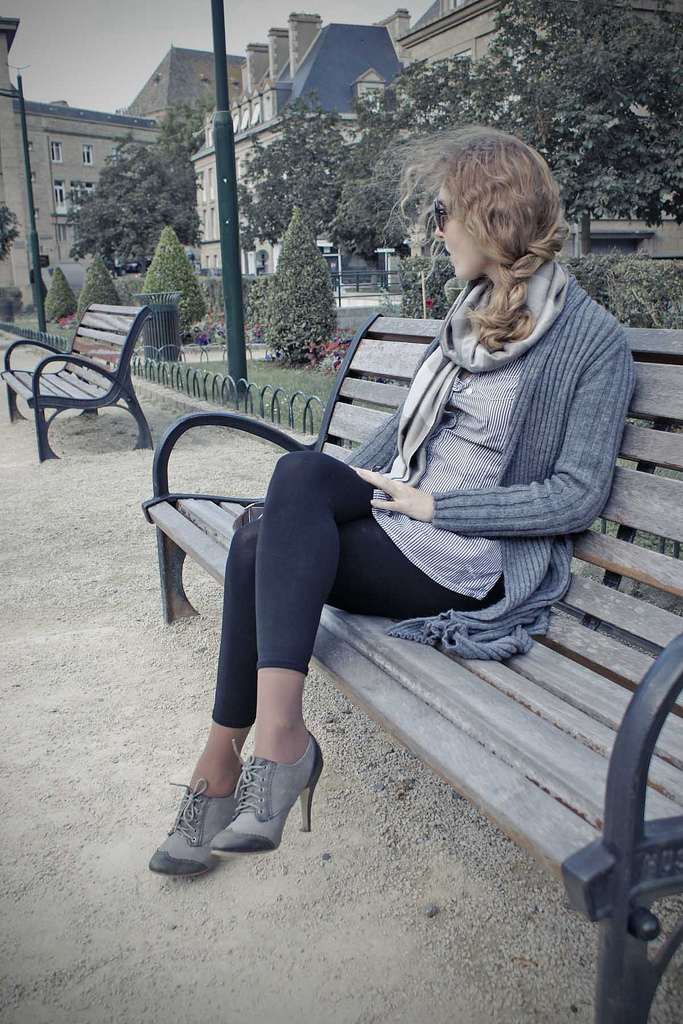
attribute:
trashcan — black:
[136, 289, 186, 360]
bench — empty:
[0, 303, 155, 460]